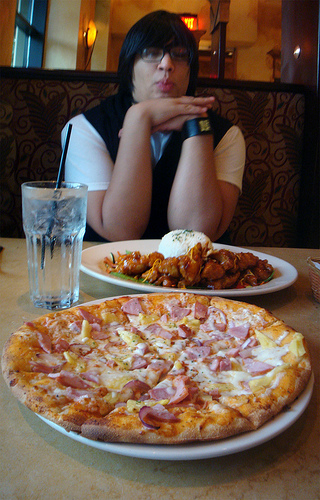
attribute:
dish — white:
[88, 247, 205, 299]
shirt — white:
[55, 101, 246, 195]